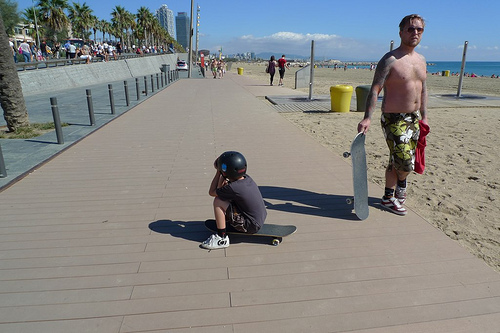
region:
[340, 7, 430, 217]
man holding a skateboard and shirt on boardwalk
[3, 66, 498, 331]
long wooden boardwalk by the beach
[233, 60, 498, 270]
sandy beach on the right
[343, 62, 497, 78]
blue ocean waters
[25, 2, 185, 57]
street lined with palm trees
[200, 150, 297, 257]
little kid sitting an a skateboard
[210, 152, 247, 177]
black skateboard helmet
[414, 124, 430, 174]
red shirt in them man's hand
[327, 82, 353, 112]
yellow trash can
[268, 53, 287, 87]
a couple arm-in-arm down the boardwalk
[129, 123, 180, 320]
walk way mad of wood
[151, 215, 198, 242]
shadow of little boy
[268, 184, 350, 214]
shadow of grown man and his skateboard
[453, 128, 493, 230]
sand on a beach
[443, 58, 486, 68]
water from the ocean of the beach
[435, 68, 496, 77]
cluster of people sitting on the sand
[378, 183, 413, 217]
shoes and socks for protection of feet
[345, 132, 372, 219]
skateboard standing upright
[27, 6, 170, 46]
palm trees aligned alongside the road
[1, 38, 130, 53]
city folk walking around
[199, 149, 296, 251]
a boy sitting on a skateboard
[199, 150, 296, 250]
a young bot sitting on a skateboard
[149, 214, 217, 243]
the shadow of a young boy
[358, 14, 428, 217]
a man standing in a goofy way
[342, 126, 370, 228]
a skateboard standing on it end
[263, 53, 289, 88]
a couple walking toward the ocean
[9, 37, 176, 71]
people on a road above the beach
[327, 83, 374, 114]
two trash barrels for different purposes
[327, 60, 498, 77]
a small piece of the ocean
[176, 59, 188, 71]
a car at beach level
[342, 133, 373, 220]
a black skateboard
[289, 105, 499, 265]
brown beach sand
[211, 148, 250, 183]
a boy's black helmet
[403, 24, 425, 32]
dark brown sunglasses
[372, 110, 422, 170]
a man's black, white and yellow shorts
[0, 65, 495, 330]
part of a long boardwalk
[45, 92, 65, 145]
a short gray pole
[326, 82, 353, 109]
a large yellow trashcan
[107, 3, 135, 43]
a tall green tree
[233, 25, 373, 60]
a large white cloud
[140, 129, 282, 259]
this is a child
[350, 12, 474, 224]
this is a person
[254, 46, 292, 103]
this is a person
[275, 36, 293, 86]
this is a person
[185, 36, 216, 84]
this is a person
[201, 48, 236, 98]
this is a person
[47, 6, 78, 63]
this is a person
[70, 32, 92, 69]
this is a person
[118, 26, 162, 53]
this is a person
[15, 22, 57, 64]
this is a person